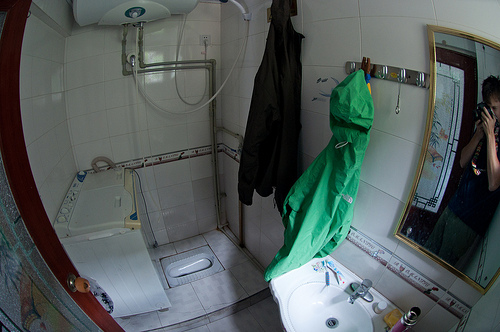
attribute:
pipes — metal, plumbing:
[117, 19, 277, 288]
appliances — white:
[53, 152, 190, 320]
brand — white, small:
[345, 195, 353, 205]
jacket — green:
[266, 70, 374, 277]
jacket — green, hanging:
[272, 62, 372, 276]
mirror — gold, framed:
[388, 17, 496, 297]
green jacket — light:
[262, 66, 374, 285]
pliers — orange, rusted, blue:
[342, 39, 393, 109]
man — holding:
[443, 90, 499, 275]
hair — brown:
[469, 77, 499, 100]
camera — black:
[469, 98, 498, 123]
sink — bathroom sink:
[206, 200, 391, 327]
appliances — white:
[62, 163, 156, 318]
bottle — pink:
[388, 305, 415, 330]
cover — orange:
[74, 277, 91, 297]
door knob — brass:
[66, 272, 92, 294]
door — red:
[2, 1, 131, 330]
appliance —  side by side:
[70, 162, 136, 188]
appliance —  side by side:
[51, 186, 163, 282]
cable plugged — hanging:
[77, 33, 336, 113]